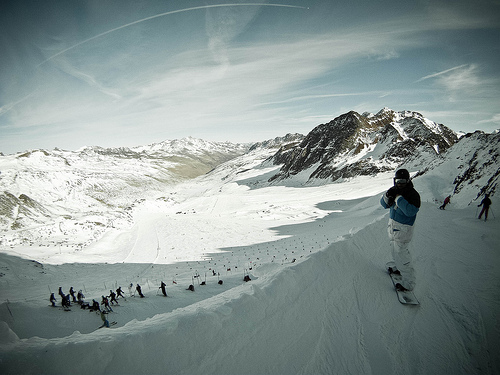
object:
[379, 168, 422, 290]
man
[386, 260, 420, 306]
snowboard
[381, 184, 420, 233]
jacket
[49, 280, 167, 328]
group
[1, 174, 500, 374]
snow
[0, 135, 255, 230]
mountain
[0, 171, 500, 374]
ski slope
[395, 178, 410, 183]
goggles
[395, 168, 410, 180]
helmet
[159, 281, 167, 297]
skier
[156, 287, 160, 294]
ski pole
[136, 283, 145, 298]
skier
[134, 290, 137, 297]
ski pole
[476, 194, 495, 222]
skier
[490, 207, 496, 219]
ski pole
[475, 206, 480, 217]
ski pole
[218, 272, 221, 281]
slalom flag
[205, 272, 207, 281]
slalom flag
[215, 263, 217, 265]
slalom flag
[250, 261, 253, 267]
slalom flag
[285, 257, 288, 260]
slalom flag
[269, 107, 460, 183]
mountain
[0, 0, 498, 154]
sky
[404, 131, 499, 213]
mountain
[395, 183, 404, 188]
mask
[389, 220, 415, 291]
pants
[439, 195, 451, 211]
skier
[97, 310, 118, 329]
skier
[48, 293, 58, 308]
skier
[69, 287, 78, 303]
skier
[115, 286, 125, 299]
skier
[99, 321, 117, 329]
skis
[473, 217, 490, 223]
skis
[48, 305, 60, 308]
skis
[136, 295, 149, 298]
skis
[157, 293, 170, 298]
skis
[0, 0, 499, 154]
clouds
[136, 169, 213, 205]
valley